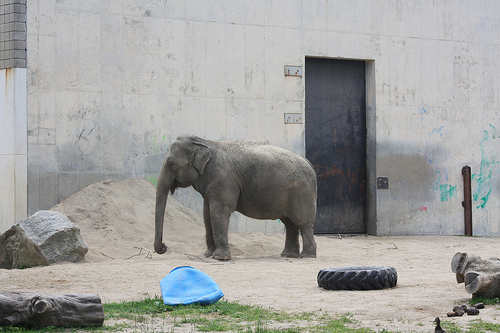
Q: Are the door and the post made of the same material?
A: Yes, both the door and the post are made of metal.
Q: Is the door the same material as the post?
A: Yes, both the door and the post are made of metal.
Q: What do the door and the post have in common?
A: The material, both the door and the post are metallic.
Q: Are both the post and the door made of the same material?
A: Yes, both the post and the door are made of metal.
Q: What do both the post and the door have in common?
A: The material, both the post and the door are metallic.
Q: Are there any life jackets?
A: No, there are no life jackets.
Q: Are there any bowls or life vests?
A: No, there are no life vests or bowls.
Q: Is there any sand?
A: Yes, there is sand.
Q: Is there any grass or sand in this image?
A: Yes, there is sand.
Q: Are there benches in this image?
A: No, there are no benches.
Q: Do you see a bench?
A: No, there are no benches.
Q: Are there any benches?
A: No, there are no benches.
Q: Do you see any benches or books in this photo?
A: No, there are no benches or books.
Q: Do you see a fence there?
A: No, there are no fences.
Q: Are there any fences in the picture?
A: No, there are no fences.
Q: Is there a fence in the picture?
A: No, there are no fences.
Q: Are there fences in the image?
A: No, there are no fences.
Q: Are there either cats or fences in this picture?
A: No, there are no fences or cats.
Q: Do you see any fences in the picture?
A: No, there are no fences.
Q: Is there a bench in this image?
A: No, there are no benches.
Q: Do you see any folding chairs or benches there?
A: No, there are no benches or folding chairs.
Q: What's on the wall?
A: The graffiti is on the wall.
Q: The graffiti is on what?
A: The graffiti is on the wall.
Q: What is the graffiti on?
A: The graffiti is on the wall.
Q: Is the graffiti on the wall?
A: Yes, the graffiti is on the wall.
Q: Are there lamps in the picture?
A: No, there are no lamps.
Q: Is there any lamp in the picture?
A: No, there are no lamps.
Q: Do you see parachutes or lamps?
A: No, there are no lamps or parachutes.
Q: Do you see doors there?
A: Yes, there is a door.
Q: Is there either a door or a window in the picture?
A: Yes, there is a door.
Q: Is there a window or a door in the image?
A: Yes, there is a door.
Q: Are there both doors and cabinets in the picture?
A: No, there is a door but no cabinets.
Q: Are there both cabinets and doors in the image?
A: No, there is a door but no cabinets.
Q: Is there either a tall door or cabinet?
A: Yes, there is a tall door.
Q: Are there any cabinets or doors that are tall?
A: Yes, the door is tall.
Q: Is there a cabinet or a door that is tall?
A: Yes, the door is tall.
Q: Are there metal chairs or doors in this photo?
A: Yes, there is a metal door.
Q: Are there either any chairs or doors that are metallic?
A: Yes, the door is metallic.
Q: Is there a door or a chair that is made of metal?
A: Yes, the door is made of metal.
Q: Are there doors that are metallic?
A: Yes, there is a door that is metallic.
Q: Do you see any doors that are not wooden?
A: Yes, there is a metallic door.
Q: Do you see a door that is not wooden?
A: Yes, there is a metallic door.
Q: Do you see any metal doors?
A: Yes, there is a door that is made of metal.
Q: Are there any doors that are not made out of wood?
A: Yes, there is a door that is made of metal.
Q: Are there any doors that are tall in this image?
A: Yes, there is a tall door.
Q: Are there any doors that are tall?
A: Yes, there is a door that is tall.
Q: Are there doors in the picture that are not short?
A: Yes, there is a tall door.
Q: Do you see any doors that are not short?
A: Yes, there is a tall door.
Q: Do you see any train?
A: No, there are no trains.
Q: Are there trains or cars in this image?
A: No, there are no trains or cars.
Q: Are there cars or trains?
A: No, there are no trains or cars.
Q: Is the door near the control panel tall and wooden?
A: No, the door is tall but metallic.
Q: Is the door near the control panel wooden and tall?
A: No, the door is tall but metallic.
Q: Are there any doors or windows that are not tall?
A: No, there is a door but it is tall.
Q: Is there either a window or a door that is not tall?
A: No, there is a door but it is tall.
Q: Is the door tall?
A: Yes, the door is tall.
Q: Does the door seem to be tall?
A: Yes, the door is tall.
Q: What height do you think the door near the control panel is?
A: The door is tall.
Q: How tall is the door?
A: The door is tall.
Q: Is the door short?
A: No, the door is tall.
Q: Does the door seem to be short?
A: No, the door is tall.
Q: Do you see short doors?
A: No, there is a door but it is tall.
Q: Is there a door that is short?
A: No, there is a door but it is tall.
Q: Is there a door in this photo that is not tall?
A: No, there is a door but it is tall.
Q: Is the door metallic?
A: Yes, the door is metallic.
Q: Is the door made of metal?
A: Yes, the door is made of metal.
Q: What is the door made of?
A: The door is made of metal.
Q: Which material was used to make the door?
A: The door is made of metal.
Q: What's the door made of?
A: The door is made of metal.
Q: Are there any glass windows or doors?
A: No, there is a door but it is metallic.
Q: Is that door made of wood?
A: No, the door is made of metal.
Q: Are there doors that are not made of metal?
A: No, there is a door but it is made of metal.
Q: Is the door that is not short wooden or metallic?
A: The door is metallic.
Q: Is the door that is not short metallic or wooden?
A: The door is metallic.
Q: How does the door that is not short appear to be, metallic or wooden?
A: The door is metallic.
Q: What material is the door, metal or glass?
A: The door is made of metal.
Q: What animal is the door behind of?
A: The door is behind the elephant.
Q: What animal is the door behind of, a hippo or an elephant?
A: The door is behind an elephant.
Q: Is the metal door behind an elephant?
A: Yes, the door is behind an elephant.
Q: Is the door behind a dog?
A: No, the door is behind an elephant.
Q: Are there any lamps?
A: No, there are no lamps.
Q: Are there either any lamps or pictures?
A: No, there are no lamps or pictures.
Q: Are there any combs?
A: No, there are no combs.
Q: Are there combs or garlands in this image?
A: No, there are no combs or garlands.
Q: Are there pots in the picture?
A: No, there are no pots.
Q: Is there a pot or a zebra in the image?
A: No, there are no pots or zebras.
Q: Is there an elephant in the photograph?
A: Yes, there is an elephant.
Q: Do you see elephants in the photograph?
A: Yes, there is an elephant.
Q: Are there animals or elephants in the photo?
A: Yes, there is an elephant.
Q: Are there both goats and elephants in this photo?
A: No, there is an elephant but no goats.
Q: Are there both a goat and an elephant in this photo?
A: No, there is an elephant but no goats.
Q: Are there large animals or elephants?
A: Yes, there is a large elephant.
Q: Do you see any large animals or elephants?
A: Yes, there is a large elephant.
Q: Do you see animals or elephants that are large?
A: Yes, the elephant is large.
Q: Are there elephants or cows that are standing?
A: Yes, the elephant is standing.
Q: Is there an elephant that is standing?
A: Yes, there is an elephant that is standing.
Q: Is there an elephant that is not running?
A: Yes, there is an elephant that is standing.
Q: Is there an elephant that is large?
A: Yes, there is an elephant that is large.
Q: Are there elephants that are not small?
A: Yes, there is a large elephant.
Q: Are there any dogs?
A: No, there are no dogs.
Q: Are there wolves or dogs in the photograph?
A: No, there are no dogs or wolves.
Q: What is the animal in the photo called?
A: The animal is an elephant.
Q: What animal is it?
A: The animal is an elephant.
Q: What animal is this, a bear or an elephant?
A: That is an elephant.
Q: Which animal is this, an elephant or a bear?
A: That is an elephant.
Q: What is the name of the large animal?
A: The animal is an elephant.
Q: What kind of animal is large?
A: The animal is an elephant.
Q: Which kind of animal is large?
A: The animal is an elephant.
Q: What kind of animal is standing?
A: The animal is an elephant.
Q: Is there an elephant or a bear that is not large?
A: No, there is an elephant but it is large.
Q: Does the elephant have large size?
A: Yes, the elephant is large.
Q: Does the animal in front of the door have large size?
A: Yes, the elephant is large.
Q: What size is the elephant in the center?
A: The elephant is large.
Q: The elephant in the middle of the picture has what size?
A: The elephant is large.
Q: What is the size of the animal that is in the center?
A: The elephant is large.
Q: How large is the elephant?
A: The elephant is large.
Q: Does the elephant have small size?
A: No, the elephant is large.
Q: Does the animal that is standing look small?
A: No, the elephant is large.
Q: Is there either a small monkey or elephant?
A: No, there is an elephant but it is large.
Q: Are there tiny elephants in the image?
A: No, there is an elephant but it is large.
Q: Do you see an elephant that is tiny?
A: No, there is an elephant but it is large.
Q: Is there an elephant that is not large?
A: No, there is an elephant but it is large.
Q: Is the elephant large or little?
A: The elephant is large.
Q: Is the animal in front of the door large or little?
A: The elephant is large.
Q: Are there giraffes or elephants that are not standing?
A: No, there is an elephant but it is standing.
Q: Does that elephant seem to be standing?
A: Yes, the elephant is standing.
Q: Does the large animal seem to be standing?
A: Yes, the elephant is standing.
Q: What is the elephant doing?
A: The elephant is standing.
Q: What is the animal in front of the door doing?
A: The elephant is standing.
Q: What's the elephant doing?
A: The elephant is standing.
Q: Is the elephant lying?
A: No, the elephant is standing.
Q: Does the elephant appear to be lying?
A: No, the elephant is standing.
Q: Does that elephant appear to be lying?
A: No, the elephant is standing.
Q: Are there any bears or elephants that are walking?
A: No, there is an elephant but it is standing.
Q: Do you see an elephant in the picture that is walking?
A: No, there is an elephant but it is standing.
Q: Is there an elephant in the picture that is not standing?
A: No, there is an elephant but it is standing.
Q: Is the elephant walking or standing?
A: The elephant is standing.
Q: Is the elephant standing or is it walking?
A: The elephant is standing.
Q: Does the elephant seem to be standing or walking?
A: The elephant is standing.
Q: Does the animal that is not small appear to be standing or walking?
A: The elephant is standing.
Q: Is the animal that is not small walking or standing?
A: The elephant is standing.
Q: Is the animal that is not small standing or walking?
A: The elephant is standing.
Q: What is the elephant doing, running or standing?
A: The elephant is standing.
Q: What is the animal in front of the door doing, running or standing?
A: The elephant is standing.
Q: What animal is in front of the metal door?
A: The elephant is in front of the door.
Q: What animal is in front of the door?
A: The elephant is in front of the door.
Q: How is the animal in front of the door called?
A: The animal is an elephant.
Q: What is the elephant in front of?
A: The elephant is in front of the door.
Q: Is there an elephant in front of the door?
A: Yes, there is an elephant in front of the door.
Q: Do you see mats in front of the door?
A: No, there is an elephant in front of the door.